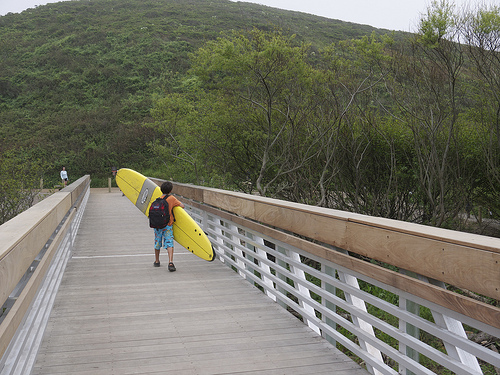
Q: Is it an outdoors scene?
A: Yes, it is outdoors.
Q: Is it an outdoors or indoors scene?
A: It is outdoors.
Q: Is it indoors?
A: No, it is outdoors.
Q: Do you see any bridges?
A: Yes, there is a bridge.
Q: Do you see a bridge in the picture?
A: Yes, there is a bridge.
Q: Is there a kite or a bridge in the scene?
A: Yes, there is a bridge.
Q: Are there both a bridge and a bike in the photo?
A: No, there is a bridge but no bikes.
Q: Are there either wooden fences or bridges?
A: Yes, there is a wood bridge.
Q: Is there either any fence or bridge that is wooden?
A: Yes, the bridge is wooden.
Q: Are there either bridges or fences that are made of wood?
A: Yes, the bridge is made of wood.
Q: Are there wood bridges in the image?
A: Yes, there is a wood bridge.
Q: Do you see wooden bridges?
A: Yes, there is a wood bridge.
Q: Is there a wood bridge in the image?
A: Yes, there is a wood bridge.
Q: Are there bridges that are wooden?
A: Yes, there is a bridge that is wooden.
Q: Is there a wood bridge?
A: Yes, there is a bridge that is made of wood.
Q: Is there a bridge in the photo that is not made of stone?
A: Yes, there is a bridge that is made of wood.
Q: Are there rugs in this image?
A: No, there are no rugs.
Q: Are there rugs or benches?
A: No, there are no rugs or benches.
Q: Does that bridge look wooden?
A: Yes, the bridge is wooden.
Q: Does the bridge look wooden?
A: Yes, the bridge is wooden.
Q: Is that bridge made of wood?
A: Yes, the bridge is made of wood.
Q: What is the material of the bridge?
A: The bridge is made of wood.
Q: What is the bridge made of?
A: The bridge is made of wood.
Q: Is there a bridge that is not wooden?
A: No, there is a bridge but it is wooden.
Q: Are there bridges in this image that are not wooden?
A: No, there is a bridge but it is wooden.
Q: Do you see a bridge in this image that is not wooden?
A: No, there is a bridge but it is wooden.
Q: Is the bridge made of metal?
A: No, the bridge is made of wood.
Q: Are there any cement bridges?
A: No, there is a bridge but it is made of wood.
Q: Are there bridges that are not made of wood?
A: No, there is a bridge but it is made of wood.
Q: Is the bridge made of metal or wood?
A: The bridge is made of wood.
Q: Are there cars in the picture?
A: No, there are no cars.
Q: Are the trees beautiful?
A: Yes, the trees are beautiful.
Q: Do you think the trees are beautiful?
A: Yes, the trees are beautiful.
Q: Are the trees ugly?
A: No, the trees are beautiful.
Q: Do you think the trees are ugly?
A: No, the trees are beautiful.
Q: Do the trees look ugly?
A: No, the trees are beautiful.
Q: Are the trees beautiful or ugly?
A: The trees are beautiful.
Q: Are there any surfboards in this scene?
A: Yes, there is a surfboard.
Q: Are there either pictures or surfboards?
A: Yes, there is a surfboard.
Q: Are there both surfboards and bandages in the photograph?
A: No, there is a surfboard but no bandages.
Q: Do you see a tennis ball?
A: No, there are no tennis balls.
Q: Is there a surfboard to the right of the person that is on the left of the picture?
A: Yes, there is a surfboard to the right of the person.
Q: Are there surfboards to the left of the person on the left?
A: No, the surfboard is to the right of the person.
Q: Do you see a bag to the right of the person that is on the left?
A: No, there is a surfboard to the right of the person.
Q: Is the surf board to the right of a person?
A: Yes, the surf board is to the right of a person.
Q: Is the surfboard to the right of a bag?
A: No, the surfboard is to the right of a person.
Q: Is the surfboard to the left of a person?
A: No, the surfboard is to the right of a person.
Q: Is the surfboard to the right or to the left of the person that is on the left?
A: The surfboard is to the right of the person.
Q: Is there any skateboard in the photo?
A: No, there are no skateboards.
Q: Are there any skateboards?
A: No, there are no skateboards.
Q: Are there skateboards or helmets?
A: No, there are no skateboards or helmets.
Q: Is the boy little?
A: Yes, the boy is little.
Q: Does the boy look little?
A: Yes, the boy is little.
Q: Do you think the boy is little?
A: Yes, the boy is little.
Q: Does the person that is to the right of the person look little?
A: Yes, the boy is little.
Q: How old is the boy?
A: The boy is little.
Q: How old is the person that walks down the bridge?
A: The boy is little.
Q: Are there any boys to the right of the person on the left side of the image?
A: Yes, there is a boy to the right of the person.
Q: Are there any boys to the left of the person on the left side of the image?
A: No, the boy is to the right of the person.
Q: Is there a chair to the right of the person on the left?
A: No, there is a boy to the right of the person.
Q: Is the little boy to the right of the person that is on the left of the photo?
A: Yes, the boy is to the right of the person.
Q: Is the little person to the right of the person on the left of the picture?
A: Yes, the boy is to the right of the person.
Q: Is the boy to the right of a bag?
A: No, the boy is to the right of the person.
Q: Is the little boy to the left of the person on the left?
A: No, the boy is to the right of the person.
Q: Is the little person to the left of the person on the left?
A: No, the boy is to the right of the person.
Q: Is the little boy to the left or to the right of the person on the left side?
A: The boy is to the right of the person.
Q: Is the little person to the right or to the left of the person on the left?
A: The boy is to the right of the person.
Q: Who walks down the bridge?
A: The boy walks down the bridge.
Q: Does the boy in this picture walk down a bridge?
A: Yes, the boy walks down a bridge.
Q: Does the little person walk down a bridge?
A: Yes, the boy walks down a bridge.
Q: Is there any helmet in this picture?
A: No, there are no helmets.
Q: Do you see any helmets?
A: No, there are no helmets.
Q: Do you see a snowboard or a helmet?
A: No, there are no helmets or snowboards.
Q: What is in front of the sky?
A: The mountain is in front of the sky.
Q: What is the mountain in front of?
A: The mountain is in front of the sky.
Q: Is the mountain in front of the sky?
A: Yes, the mountain is in front of the sky.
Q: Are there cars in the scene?
A: No, there are no cars.